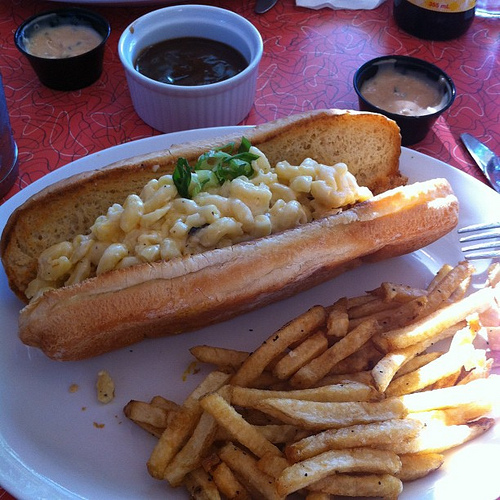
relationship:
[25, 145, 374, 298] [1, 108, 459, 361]
macaroni inside bun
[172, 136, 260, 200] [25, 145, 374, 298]
garnish on macaroni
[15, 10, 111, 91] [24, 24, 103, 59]
cup contains sauce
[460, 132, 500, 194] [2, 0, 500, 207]
knife lays on table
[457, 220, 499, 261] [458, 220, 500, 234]
fork has a prong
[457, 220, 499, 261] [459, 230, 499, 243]
fork has a prong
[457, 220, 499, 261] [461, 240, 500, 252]
fork has a prong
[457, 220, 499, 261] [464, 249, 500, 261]
fork has a prong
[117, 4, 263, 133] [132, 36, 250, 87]
cup contains sauce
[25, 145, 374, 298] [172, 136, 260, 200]
macaroni has a garnish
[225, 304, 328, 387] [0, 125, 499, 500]
fry on a plate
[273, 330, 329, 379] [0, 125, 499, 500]
fry on a plate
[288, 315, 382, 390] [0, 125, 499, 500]
fry on a plate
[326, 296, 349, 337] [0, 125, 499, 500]
fry on a plate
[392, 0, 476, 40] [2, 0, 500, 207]
bottle on table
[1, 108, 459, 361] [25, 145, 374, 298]
bun has macaroni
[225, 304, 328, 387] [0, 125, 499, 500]
fry on plate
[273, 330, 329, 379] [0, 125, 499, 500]
fry on plate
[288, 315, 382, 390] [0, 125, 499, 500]
fry on plate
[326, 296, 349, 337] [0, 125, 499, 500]
fry on plate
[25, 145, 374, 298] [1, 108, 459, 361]
macaroni in bun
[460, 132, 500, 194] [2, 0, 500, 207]
knife on table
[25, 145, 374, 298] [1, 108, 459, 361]
macaroni on bun